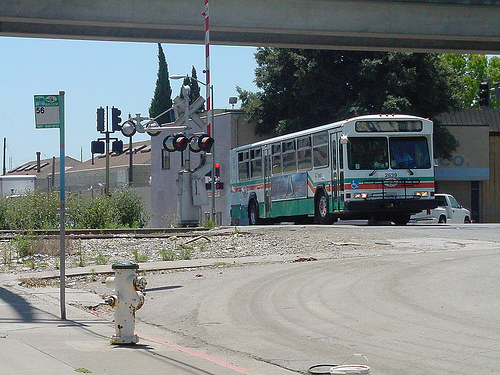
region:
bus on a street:
[221, 107, 447, 234]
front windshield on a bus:
[341, 132, 435, 173]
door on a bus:
[324, 123, 349, 218]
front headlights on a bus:
[350, 190, 371, 204]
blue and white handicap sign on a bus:
[348, 177, 360, 192]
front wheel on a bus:
[310, 184, 339, 226]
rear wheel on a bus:
[243, 195, 261, 230]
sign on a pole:
[28, 85, 71, 137]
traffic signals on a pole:
[87, 100, 127, 138]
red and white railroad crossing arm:
[197, 0, 214, 157]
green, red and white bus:
[222, 110, 438, 234]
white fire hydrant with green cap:
[97, 258, 147, 346]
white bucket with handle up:
[329, 352, 371, 374]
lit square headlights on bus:
[353, 190, 430, 200]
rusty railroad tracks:
[5, 220, 211, 239]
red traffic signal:
[212, 160, 221, 177]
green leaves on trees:
[232, 45, 497, 141]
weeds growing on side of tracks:
[3, 181, 148, 229]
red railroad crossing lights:
[120, 114, 215, 154]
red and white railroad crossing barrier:
[202, 27, 214, 139]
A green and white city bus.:
[226, 106, 443, 231]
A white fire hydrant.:
[104, 255, 149, 348]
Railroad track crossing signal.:
[167, 123, 219, 227]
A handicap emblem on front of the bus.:
[347, 172, 361, 189]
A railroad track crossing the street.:
[6, 215, 490, 245]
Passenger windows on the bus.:
[236, 128, 329, 179]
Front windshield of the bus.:
[344, 125, 432, 172]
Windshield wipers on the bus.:
[354, 146, 426, 181]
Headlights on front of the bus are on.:
[350, 187, 434, 200]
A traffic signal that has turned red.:
[206, 157, 226, 189]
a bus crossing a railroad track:
[164, 110, 441, 225]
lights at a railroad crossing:
[158, 125, 220, 162]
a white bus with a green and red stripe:
[220, 112, 431, 219]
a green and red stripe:
[230, 175, 437, 198]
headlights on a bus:
[348, 183, 433, 203]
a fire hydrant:
[95, 253, 155, 353]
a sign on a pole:
[30, 90, 74, 315]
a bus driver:
[393, 143, 419, 167]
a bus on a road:
[221, 104, 476, 257]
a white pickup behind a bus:
[420, 187, 477, 233]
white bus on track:
[280, 128, 449, 252]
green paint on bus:
[335, 165, 383, 186]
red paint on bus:
[360, 182, 392, 196]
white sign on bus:
[354, 172, 361, 190]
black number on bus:
[387, 163, 406, 179]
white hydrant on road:
[89, 224, 163, 371]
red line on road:
[166, 327, 202, 367]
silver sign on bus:
[268, 165, 309, 198]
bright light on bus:
[345, 185, 385, 200]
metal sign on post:
[19, 50, 87, 153]